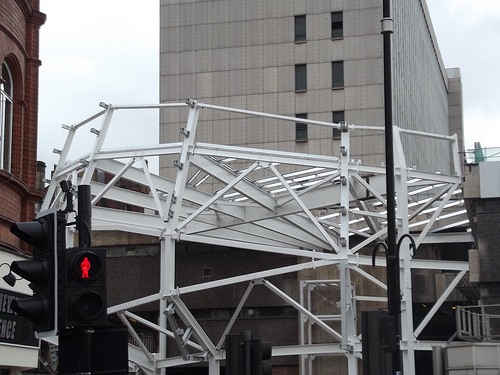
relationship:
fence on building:
[463, 140, 488, 158] [170, 4, 323, 109]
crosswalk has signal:
[28, 174, 194, 374] [69, 239, 128, 313]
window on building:
[2, 54, 34, 105] [170, 4, 323, 109]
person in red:
[64, 244, 101, 282] [72, 268, 108, 285]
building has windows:
[170, 4, 323, 109] [260, 15, 362, 130]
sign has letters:
[2, 284, 32, 338] [171, 324, 259, 370]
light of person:
[52, 241, 142, 316] [79, 255, 93, 278]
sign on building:
[2, 284, 32, 338] [170, 4, 323, 109]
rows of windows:
[282, 49, 385, 102] [260, 15, 362, 130]